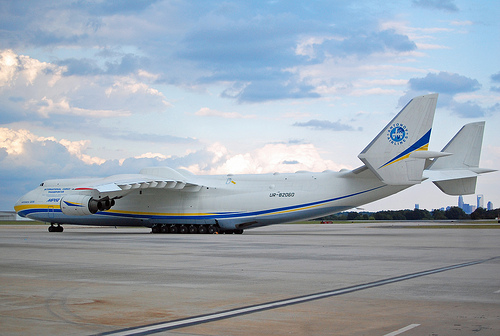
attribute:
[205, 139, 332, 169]
clouds — white , gray, big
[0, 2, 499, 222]
sky — blue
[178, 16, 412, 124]
sky — blue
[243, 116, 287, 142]
sky — blue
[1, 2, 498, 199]
sky — blue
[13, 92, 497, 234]
airplane — White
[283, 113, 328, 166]
ground — gray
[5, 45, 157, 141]
clouds — white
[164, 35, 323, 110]
sky — blue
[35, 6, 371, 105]
clouds — gray, white, big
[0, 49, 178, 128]
cloud — white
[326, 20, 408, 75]
sky — blue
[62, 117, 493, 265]
airplane — white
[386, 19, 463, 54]
cloud — white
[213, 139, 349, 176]
cloud — white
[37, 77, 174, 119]
cloud — white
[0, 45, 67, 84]
cloud — white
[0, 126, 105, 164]
cloud — white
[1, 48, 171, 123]
clouds — white, big, gray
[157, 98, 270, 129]
sky — blue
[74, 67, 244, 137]
clouds — big, white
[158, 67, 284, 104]
sky — blue